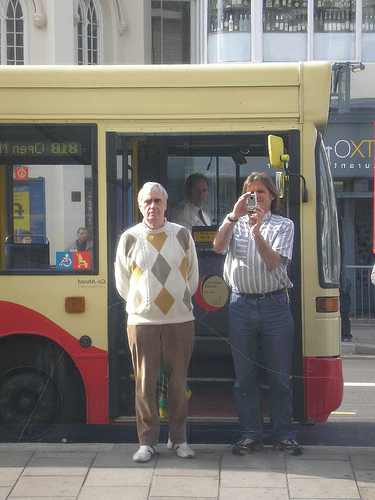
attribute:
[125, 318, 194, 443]
pants — brown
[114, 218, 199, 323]
sweater — white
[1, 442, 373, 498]
sidewalk — grey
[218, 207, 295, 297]
shirt — grey, white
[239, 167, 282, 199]
hair — brown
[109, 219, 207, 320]
sweater — argyle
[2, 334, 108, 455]
tire — black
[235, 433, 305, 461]
shoes — black